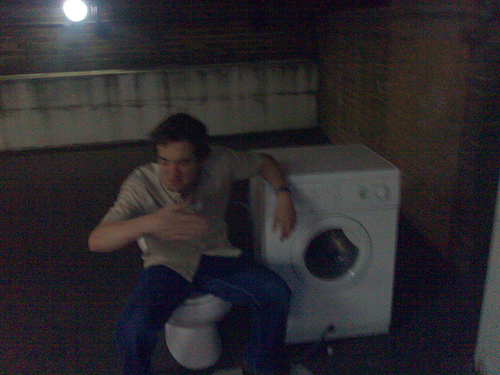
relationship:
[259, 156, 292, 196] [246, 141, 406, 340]
forearm near appliance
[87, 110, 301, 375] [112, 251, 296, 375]
man wearing jeans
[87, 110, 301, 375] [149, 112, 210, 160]
man with hair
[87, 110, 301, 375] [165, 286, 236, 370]
man sitting on toilet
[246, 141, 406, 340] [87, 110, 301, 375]
appliance near man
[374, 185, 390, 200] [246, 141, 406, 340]
knob of appliance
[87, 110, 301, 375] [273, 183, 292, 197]
man wearing watch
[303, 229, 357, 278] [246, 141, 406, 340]
window of appliance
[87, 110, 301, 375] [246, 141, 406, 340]
man leaning on appliance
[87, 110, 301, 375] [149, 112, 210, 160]
man has hair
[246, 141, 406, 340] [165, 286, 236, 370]
appliance near toilet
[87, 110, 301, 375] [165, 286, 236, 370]
man on top of toilet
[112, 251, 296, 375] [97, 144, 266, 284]
jeans with shirt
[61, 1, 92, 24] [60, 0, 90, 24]
light on wall